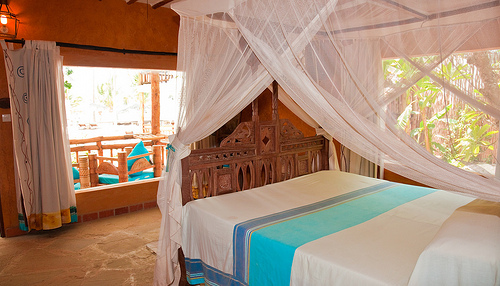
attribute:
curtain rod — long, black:
[0, 37, 180, 59]